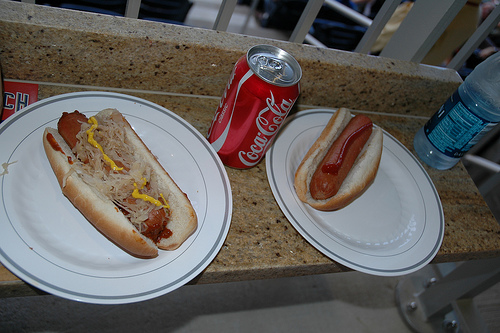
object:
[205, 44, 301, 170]
can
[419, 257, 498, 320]
leg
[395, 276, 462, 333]
base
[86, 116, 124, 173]
mustard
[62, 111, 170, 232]
sauerkraut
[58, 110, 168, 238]
hot dog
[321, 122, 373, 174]
ketchup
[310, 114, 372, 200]
hot dog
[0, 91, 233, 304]
plate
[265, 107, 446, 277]
plate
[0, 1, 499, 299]
counter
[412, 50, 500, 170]
bottle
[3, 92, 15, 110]
c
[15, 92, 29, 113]
h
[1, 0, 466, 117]
ledge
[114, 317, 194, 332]
shadow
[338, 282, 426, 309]
shadow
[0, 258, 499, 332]
floor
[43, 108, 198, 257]
bun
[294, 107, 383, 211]
bun